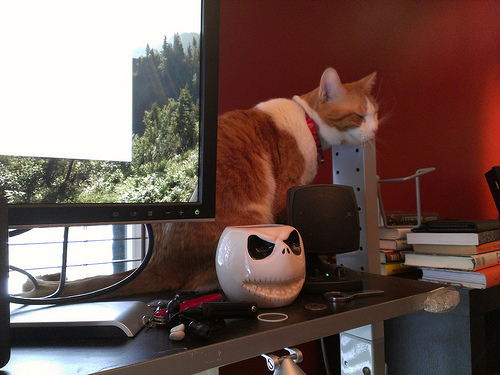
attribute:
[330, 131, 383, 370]
rod — iron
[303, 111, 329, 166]
collar —  red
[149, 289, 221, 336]
knife — red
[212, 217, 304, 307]
mug — scary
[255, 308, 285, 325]
rubber band — plain, white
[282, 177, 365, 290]
speaker — small, black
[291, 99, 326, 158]
collar — red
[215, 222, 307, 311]
object — white, black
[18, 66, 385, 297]
cat — brown, orange, white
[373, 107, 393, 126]
whiskers — long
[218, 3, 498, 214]
wall — orange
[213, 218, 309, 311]
mug — white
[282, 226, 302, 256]
eye — black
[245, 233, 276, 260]
eye — black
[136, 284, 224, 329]
knife — red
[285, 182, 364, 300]
speaker — black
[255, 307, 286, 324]
rubber band — small, pink, circular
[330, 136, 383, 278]
post — white, metal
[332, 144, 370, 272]
holes — small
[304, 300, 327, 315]
quarter — silver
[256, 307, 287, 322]
hair band — white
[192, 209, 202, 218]
power button — yellow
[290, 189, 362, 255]
speaker — black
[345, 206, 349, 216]
light — tiny, green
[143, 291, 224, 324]
pocket knife — deep, red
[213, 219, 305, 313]
bowl — white, black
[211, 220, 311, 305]
container — black, white, ceramic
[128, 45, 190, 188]
scene — nature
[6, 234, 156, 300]
wire — thick, black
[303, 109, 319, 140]
collar — red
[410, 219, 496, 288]
books — two piles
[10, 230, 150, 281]
window — slatted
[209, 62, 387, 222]
cat — brown, white, orange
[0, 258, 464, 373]
desk — black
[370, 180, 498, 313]
books — stacked, in corner